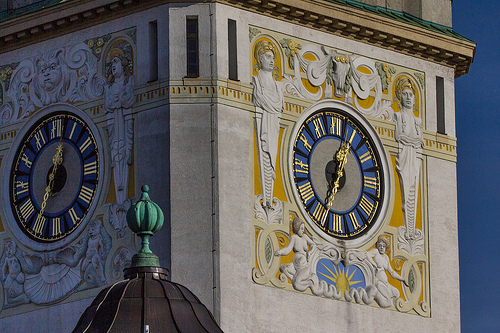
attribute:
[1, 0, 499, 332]
tower — stone, historical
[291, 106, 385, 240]
clock — blue, white, grey, blue yellow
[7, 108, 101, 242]
clock — blue, white, grey, blue yellow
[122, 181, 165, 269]
top — green, decorative, historical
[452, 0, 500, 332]
sky — bright, blue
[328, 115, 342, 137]
number — roman, gold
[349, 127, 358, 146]
number — roman, gold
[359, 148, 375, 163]
number — roman, gold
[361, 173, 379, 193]
number — roman, gold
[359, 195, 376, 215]
number — roman, gold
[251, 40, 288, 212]
woman — sculpted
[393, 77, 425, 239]
woman — sculpted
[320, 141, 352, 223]
hands — gold, yellow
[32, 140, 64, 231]
hands — gold, yellow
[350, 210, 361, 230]
number — roman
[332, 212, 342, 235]
number — roman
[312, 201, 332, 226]
number — roman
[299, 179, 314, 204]
number — roman